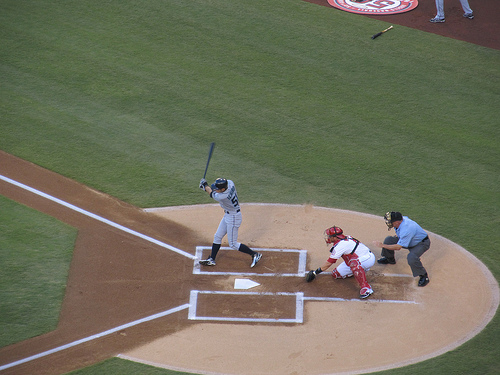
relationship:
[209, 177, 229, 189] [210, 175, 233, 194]
helmet on head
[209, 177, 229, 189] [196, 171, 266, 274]
helmet on batter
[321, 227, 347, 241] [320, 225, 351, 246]
helmet on catcher's head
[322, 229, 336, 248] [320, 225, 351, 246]
mask on catcher's head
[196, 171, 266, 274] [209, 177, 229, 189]
ichiro has helmet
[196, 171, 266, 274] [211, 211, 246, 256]
player has pants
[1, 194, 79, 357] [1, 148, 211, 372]
grass in infield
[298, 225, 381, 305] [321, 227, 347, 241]
catcher has helmet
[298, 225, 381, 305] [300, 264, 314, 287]
catcher has glove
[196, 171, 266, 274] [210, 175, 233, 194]
person has head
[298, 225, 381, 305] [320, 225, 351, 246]
catcher has head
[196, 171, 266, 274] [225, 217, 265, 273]
person has leg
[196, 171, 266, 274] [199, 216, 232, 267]
person has leg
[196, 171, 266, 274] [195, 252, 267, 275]
person has feet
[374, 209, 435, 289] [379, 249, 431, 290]
person has feet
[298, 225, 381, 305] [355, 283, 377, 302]
catcher has feet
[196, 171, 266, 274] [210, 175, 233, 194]
batter has head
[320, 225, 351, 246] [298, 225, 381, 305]
head of catcher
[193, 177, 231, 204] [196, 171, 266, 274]
arm of batter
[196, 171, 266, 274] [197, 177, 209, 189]
batter has a hand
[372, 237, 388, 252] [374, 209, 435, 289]
hand of a person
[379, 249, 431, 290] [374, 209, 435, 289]
feet of person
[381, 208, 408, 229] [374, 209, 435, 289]
head of person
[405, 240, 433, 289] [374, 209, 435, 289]
leg of a person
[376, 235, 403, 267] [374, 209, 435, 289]
leg of a person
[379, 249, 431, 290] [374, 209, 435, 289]
feet of a person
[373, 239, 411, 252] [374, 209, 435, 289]
arm of a person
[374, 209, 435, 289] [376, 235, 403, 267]
person has leg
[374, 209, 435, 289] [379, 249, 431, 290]
man in shoes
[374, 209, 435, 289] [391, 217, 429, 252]
person in shirt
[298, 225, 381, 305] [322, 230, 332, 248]
catcher wearing mask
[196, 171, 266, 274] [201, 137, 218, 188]
player holding bat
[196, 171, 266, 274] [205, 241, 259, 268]
batter wearing socks